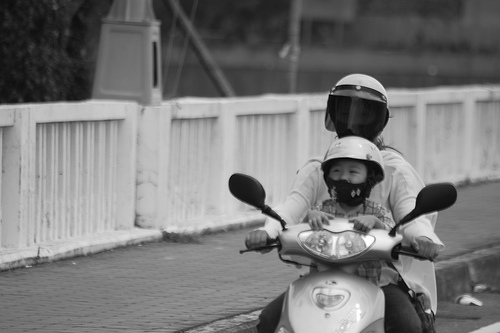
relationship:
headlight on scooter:
[295, 226, 375, 261] [229, 171, 444, 329]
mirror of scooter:
[214, 162, 291, 222] [214, 181, 479, 331]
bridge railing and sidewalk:
[2, 97, 252, 265] [0, 180, 500, 331]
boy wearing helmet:
[319, 134, 384, 234] [312, 68, 402, 182]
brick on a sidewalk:
[132, 284, 143, 302] [14, 159, 488, 331]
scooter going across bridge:
[220, 198, 471, 323] [7, 84, 498, 328]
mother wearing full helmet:
[245, 72, 439, 332] [326, 70, 389, 139]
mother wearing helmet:
[245, 72, 439, 332] [323, 70, 388, 137]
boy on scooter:
[302, 134, 397, 287] [214, 205, 467, 328]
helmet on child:
[319, 142, 381, 160] [308, 149, 390, 223]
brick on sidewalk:
[16, 277, 30, 285] [0, 180, 500, 331]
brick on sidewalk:
[37, 264, 64, 278] [6, 261, 261, 314]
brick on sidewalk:
[82, 303, 96, 317] [33, 250, 251, 324]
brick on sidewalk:
[138, 290, 148, 300] [0, 180, 500, 331]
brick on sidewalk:
[155, 241, 242, 301] [0, 180, 500, 331]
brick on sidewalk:
[198, 287, 217, 293] [0, 180, 500, 331]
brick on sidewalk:
[199, 312, 221, 320] [0, 180, 500, 331]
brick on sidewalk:
[238, 293, 263, 302] [0, 180, 500, 331]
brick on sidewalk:
[153, 325, 178, 331] [0, 180, 500, 331]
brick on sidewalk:
[159, 300, 181, 308] [0, 180, 500, 331]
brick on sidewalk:
[184, 265, 193, 270] [0, 180, 500, 331]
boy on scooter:
[302, 134, 397, 287] [223, 171, 470, 331]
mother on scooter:
[245, 72, 439, 332] [223, 171, 470, 331]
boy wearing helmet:
[302, 134, 397, 287] [319, 144, 391, 208]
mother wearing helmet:
[245, 72, 439, 332] [317, 70, 396, 140]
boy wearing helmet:
[302, 134, 397, 287] [321, 130, 386, 205]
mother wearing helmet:
[245, 72, 439, 332] [312, 65, 398, 142]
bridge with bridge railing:
[2, 6, 498, 283] [0, 84, 499, 270]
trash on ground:
[454, 279, 499, 312] [4, 196, 497, 330]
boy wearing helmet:
[302, 134, 397, 287] [308, 51, 448, 156]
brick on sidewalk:
[160, 312, 188, 322] [0, 227, 287, 331]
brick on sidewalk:
[164, 266, 239, 308] [80, 239, 226, 311]